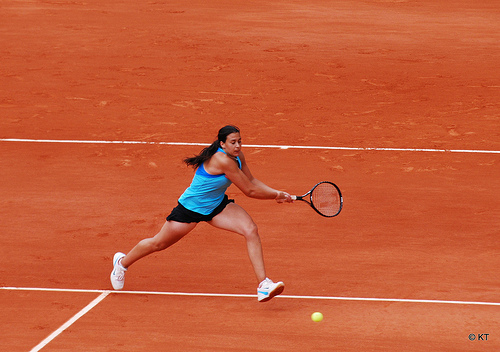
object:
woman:
[110, 125, 283, 304]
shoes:
[109, 254, 127, 290]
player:
[108, 123, 287, 302]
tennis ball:
[309, 311, 321, 321]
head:
[218, 124, 242, 154]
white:
[3, 137, 495, 156]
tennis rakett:
[278, 181, 342, 219]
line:
[1, 136, 498, 153]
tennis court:
[1, 0, 496, 350]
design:
[257, 287, 268, 295]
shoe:
[254, 276, 285, 303]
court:
[299, 103, 491, 345]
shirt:
[176, 150, 243, 214]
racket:
[289, 179, 342, 218]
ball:
[311, 311, 322, 322]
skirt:
[176, 146, 242, 215]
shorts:
[168, 189, 232, 223]